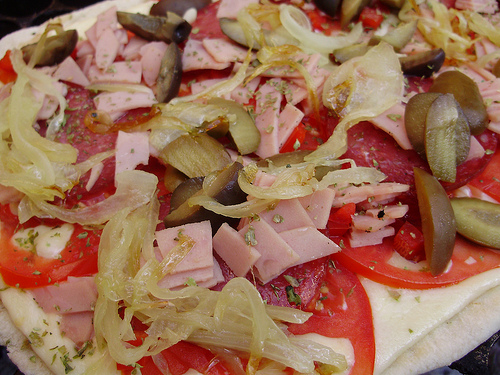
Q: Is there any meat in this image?
A: Yes, there is meat.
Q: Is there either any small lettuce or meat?
A: Yes, there is small meat.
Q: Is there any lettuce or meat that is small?
A: Yes, the meat is small.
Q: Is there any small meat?
A: Yes, there is small meat.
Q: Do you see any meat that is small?
A: Yes, there is meat that is small.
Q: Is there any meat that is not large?
A: Yes, there is small meat.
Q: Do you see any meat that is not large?
A: Yes, there is small meat.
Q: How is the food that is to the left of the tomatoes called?
A: The food is meat.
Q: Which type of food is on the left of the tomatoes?
A: The food is meat.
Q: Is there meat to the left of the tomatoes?
A: Yes, there is meat to the left of the tomatoes.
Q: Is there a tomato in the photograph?
A: Yes, there are tomatoes.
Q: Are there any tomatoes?
A: Yes, there are tomatoes.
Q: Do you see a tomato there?
A: Yes, there are tomatoes.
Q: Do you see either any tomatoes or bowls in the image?
A: Yes, there are tomatoes.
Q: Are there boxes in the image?
A: No, there are no boxes.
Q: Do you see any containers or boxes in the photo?
A: No, there are no boxes or containers.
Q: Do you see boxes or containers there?
A: No, there are no boxes or containers.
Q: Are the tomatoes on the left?
A: No, the tomatoes are on the right of the image.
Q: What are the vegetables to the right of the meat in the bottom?
A: The vegetables are tomatoes.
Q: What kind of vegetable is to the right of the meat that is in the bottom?
A: The vegetables are tomatoes.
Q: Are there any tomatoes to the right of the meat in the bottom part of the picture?
A: Yes, there are tomatoes to the right of the meat.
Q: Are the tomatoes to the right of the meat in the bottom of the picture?
A: Yes, the tomatoes are to the right of the meat.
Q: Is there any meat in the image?
A: Yes, there is meat.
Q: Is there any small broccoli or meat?
A: Yes, there is small meat.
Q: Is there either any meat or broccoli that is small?
A: Yes, the meat is small.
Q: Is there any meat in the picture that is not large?
A: Yes, there is small meat.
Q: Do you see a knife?
A: No, there are no knives.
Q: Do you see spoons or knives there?
A: No, there are no knives or spoons.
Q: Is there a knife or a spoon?
A: No, there are no knives or spoons.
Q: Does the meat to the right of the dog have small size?
A: Yes, the meat is small.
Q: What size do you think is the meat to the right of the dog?
A: The meat is small.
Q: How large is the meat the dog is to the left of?
A: The meat is small.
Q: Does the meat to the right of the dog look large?
A: No, the meat is small.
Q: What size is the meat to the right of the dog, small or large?
A: The meat is small.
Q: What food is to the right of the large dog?
A: The food is meat.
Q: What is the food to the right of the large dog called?
A: The food is meat.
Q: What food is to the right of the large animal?
A: The food is meat.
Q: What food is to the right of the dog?
A: The food is meat.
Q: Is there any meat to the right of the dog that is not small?
A: Yes, there is meat to the right of the dog.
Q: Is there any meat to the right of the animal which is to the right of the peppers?
A: Yes, there is meat to the right of the dog.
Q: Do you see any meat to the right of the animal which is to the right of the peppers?
A: Yes, there is meat to the right of the dog.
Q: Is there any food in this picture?
A: Yes, there is food.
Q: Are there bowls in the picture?
A: No, there are no bowls.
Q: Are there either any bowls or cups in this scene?
A: No, there are no bowls or cups.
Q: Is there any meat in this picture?
A: Yes, there is meat.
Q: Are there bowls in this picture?
A: No, there are no bowls.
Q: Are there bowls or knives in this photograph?
A: No, there are no bowls or knives.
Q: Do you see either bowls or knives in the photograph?
A: No, there are no bowls or knives.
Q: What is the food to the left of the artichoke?
A: The food is meat.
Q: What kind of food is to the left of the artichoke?
A: The food is meat.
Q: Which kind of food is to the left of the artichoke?
A: The food is meat.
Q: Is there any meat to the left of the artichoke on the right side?
A: Yes, there is meat to the left of the artichoke.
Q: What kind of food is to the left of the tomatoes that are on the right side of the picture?
A: The food is meat.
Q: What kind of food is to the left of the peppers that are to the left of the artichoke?
A: The food is meat.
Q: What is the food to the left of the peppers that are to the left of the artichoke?
A: The food is meat.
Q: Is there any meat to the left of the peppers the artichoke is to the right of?
A: Yes, there is meat to the left of the peppers.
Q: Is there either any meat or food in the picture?
A: Yes, there is meat.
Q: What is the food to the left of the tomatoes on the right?
A: The food is meat.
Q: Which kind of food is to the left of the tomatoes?
A: The food is meat.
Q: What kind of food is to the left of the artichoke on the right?
A: The food is meat.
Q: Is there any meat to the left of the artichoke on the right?
A: Yes, there is meat to the left of the artichoke.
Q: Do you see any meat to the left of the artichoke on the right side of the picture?
A: Yes, there is meat to the left of the artichoke.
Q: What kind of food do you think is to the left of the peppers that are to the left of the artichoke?
A: The food is meat.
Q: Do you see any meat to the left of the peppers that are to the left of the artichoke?
A: Yes, there is meat to the left of the peppers.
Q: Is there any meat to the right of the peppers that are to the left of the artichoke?
A: No, the meat is to the left of the peppers.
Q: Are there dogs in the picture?
A: Yes, there is a dog.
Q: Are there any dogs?
A: Yes, there is a dog.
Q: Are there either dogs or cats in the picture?
A: Yes, there is a dog.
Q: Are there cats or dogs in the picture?
A: Yes, there is a dog.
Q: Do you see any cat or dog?
A: Yes, there is a dog.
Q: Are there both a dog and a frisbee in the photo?
A: No, there is a dog but no frisbees.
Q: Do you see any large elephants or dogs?
A: Yes, there is a large dog.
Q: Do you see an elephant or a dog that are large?
A: Yes, the dog is large.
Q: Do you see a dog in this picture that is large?
A: Yes, there is a large dog.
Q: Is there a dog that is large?
A: Yes, there is a dog that is large.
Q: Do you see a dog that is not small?
A: Yes, there is a large dog.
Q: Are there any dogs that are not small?
A: Yes, there is a large dog.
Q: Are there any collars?
A: No, there are no collars.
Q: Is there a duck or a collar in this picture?
A: No, there are no collars or ducks.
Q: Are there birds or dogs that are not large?
A: No, there is a dog but it is large.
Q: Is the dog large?
A: Yes, the dog is large.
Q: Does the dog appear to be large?
A: Yes, the dog is large.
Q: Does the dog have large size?
A: Yes, the dog is large.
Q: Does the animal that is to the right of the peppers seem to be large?
A: Yes, the dog is large.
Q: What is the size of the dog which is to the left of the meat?
A: The dog is large.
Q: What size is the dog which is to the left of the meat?
A: The dog is large.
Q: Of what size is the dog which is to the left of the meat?
A: The dog is large.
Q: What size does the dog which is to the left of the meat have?
A: The dog has large size.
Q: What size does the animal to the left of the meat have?
A: The dog has large size.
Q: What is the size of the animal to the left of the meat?
A: The dog is large.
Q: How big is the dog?
A: The dog is large.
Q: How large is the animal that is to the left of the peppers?
A: The dog is large.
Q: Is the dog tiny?
A: No, the dog is large.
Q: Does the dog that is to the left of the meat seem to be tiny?
A: No, the dog is large.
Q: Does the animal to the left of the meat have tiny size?
A: No, the dog is large.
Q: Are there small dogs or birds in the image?
A: No, there is a dog but it is large.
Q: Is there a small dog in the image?
A: No, there is a dog but it is large.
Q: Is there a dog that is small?
A: No, there is a dog but it is large.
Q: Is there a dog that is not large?
A: No, there is a dog but it is large.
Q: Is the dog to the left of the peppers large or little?
A: The dog is large.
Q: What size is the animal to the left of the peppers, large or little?
A: The dog is large.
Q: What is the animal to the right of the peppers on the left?
A: The animal is a dog.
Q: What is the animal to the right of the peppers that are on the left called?
A: The animal is a dog.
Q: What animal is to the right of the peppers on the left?
A: The animal is a dog.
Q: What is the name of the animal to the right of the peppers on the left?
A: The animal is a dog.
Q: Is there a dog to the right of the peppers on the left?
A: Yes, there is a dog to the right of the peppers.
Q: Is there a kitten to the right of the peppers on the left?
A: No, there is a dog to the right of the peppers.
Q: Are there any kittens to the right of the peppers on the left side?
A: No, there is a dog to the right of the peppers.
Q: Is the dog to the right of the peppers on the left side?
A: Yes, the dog is to the right of the peppers.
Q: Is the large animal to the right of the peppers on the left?
A: Yes, the dog is to the right of the peppers.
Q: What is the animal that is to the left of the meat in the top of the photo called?
A: The animal is a dog.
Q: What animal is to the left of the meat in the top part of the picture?
A: The animal is a dog.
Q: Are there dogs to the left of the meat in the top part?
A: Yes, there is a dog to the left of the meat.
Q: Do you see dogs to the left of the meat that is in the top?
A: Yes, there is a dog to the left of the meat.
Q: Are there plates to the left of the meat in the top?
A: No, there is a dog to the left of the meat.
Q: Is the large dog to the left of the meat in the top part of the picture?
A: Yes, the dog is to the left of the meat.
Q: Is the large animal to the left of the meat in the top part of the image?
A: Yes, the dog is to the left of the meat.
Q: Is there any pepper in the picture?
A: Yes, there are peppers.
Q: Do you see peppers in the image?
A: Yes, there are peppers.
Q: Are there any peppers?
A: Yes, there are peppers.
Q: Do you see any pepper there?
A: Yes, there are peppers.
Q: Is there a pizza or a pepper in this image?
A: Yes, there are peppers.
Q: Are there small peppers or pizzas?
A: Yes, there are small peppers.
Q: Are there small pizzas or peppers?
A: Yes, there are small peppers.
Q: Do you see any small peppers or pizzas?
A: Yes, there are small peppers.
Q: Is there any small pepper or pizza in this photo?
A: Yes, there are small peppers.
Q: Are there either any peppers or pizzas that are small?
A: Yes, the peppers are small.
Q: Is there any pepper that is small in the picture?
A: Yes, there are small peppers.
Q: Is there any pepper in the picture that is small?
A: Yes, there are peppers that are small.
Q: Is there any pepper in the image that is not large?
A: Yes, there are small peppers.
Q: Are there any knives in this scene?
A: No, there are no knives.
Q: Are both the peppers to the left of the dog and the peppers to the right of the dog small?
A: Yes, both the peppers and the peppers are small.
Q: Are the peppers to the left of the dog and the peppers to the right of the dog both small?
A: Yes, both the peppers and the peppers are small.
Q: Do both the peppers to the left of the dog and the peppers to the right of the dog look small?
A: Yes, both the peppers and the peppers are small.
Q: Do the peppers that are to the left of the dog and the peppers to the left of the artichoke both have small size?
A: Yes, both the peppers and the peppers are small.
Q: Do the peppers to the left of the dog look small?
A: Yes, the peppers are small.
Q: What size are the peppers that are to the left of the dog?
A: The peppers are small.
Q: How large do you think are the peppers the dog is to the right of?
A: The peppers are small.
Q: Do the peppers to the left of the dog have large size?
A: No, the peppers are small.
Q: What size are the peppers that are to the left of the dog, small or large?
A: The peppers are small.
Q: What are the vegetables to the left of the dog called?
A: The vegetables are peppers.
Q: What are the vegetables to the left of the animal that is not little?
A: The vegetables are peppers.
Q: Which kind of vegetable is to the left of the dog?
A: The vegetables are peppers.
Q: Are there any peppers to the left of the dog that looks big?
A: Yes, there are peppers to the left of the dog.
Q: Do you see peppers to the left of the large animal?
A: Yes, there are peppers to the left of the dog.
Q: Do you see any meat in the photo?
A: Yes, there is meat.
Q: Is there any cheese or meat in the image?
A: Yes, there is meat.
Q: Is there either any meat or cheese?
A: Yes, there is meat.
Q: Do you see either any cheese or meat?
A: Yes, there is meat.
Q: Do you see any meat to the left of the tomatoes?
A: Yes, there is meat to the left of the tomatoes.